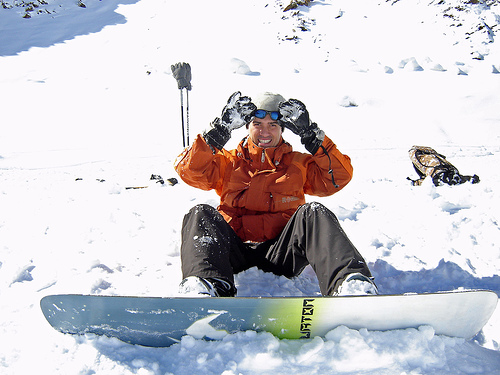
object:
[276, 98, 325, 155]
glove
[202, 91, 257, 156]
glove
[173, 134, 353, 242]
jacket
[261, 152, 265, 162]
zipper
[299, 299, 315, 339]
words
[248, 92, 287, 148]
head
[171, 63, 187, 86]
glove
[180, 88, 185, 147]
ski pole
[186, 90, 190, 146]
ski pole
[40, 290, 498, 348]
board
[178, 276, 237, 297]
boot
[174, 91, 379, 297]
man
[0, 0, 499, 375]
snow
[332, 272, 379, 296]
snow boot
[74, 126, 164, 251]
ground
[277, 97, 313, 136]
hand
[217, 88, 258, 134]
hand